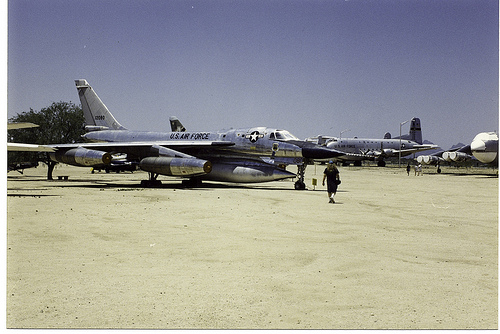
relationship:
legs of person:
[323, 183, 340, 202] [321, 159, 342, 201]